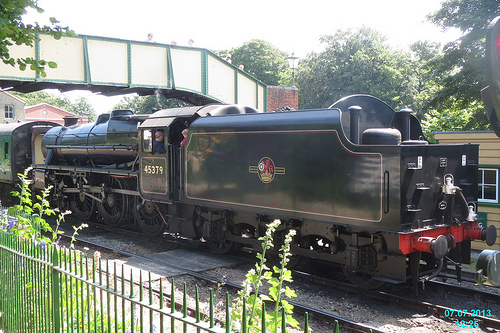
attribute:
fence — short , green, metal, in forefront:
[1, 225, 356, 332]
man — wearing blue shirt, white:
[150, 132, 162, 154]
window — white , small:
[468, 154, 498, 207]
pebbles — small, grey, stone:
[321, 294, 363, 316]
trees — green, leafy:
[299, 39, 446, 123]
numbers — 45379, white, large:
[141, 162, 166, 175]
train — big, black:
[32, 90, 494, 300]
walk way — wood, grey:
[95, 243, 249, 284]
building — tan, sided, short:
[430, 128, 498, 253]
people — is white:
[142, 32, 158, 44]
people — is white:
[169, 35, 179, 46]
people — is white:
[184, 37, 196, 47]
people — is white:
[220, 52, 233, 64]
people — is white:
[236, 64, 246, 72]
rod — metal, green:
[76, 252, 86, 331]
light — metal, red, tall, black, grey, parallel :
[482, 14, 498, 134]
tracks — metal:
[85, 229, 492, 329]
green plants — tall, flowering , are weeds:
[6, 175, 94, 265]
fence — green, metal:
[6, 235, 137, 332]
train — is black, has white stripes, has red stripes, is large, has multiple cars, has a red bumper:
[15, 67, 499, 318]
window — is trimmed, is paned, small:
[477, 164, 497, 204]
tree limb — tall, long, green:
[4, 13, 79, 44]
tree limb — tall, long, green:
[0, 45, 57, 82]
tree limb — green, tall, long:
[411, 52, 468, 79]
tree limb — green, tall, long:
[458, 106, 490, 134]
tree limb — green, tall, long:
[422, 5, 487, 32]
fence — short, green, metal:
[2, 218, 340, 330]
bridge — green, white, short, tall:
[0, 21, 279, 120]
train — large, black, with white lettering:
[15, 94, 499, 311]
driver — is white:
[149, 132, 169, 157]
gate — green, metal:
[5, 238, 191, 330]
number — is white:
[140, 160, 165, 177]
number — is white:
[140, 160, 150, 177]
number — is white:
[145, 162, 152, 174]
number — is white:
[148, 162, 156, 175]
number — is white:
[153, 163, 160, 176]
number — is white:
[155, 162, 163, 175]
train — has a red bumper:
[88, 52, 458, 262]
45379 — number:
[142, 162, 166, 177]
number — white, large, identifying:
[135, 164, 169, 179]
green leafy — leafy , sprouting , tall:
[14, 163, 54, 245]